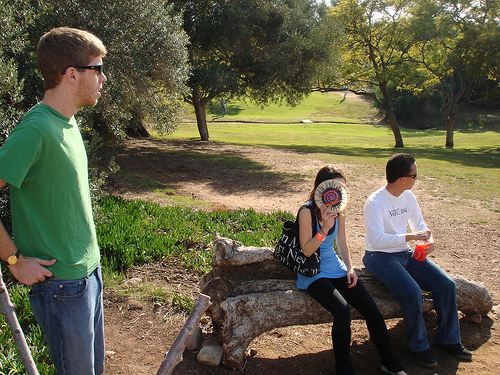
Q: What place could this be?
A: It is a path.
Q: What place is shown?
A: It is a path.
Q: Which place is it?
A: It is a path.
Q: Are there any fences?
A: No, there are no fences.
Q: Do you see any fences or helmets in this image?
A: No, there are no fences or helmets.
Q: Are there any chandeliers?
A: No, there are no chandeliers.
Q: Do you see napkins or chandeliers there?
A: No, there are no chandeliers or napkins.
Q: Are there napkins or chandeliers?
A: No, there are no chandeliers or napkins.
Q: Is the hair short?
A: Yes, the hair is short.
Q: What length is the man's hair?
A: The hair is short.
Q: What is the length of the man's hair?
A: The hair is short.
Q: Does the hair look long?
A: No, the hair is short.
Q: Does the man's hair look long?
A: No, the hair is short.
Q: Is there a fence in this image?
A: No, there are no fences.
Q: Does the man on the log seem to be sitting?
A: Yes, the man is sitting.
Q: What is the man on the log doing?
A: The man is sitting.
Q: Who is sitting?
A: The man is sitting.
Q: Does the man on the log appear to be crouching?
A: No, the man is sitting.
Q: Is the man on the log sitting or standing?
A: The man is sitting.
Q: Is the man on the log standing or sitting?
A: The man is sitting.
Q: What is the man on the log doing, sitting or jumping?
A: The man is sitting.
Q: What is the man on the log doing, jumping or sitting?
A: The man is sitting.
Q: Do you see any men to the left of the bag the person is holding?
A: No, the man is to the right of the bag.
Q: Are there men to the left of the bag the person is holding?
A: No, the man is to the right of the bag.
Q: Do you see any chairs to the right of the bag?
A: No, there is a man to the right of the bag.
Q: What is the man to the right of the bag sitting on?
A: The man is sitting on the log.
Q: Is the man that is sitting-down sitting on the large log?
A: Yes, the man is sitting on the log.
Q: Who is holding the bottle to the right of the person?
A: The man is holding the bottle.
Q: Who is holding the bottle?
A: The man is holding the bottle.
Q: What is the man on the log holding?
A: The man is holding the bottle.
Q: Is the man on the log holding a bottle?
A: Yes, the man is holding a bottle.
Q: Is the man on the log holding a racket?
A: No, the man is holding a bottle.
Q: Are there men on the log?
A: Yes, there is a man on the log.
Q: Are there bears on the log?
A: No, there is a man on the log.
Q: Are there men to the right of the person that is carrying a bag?
A: Yes, there is a man to the right of the person.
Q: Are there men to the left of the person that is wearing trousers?
A: No, the man is to the right of the person.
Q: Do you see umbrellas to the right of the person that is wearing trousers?
A: No, there is a man to the right of the person.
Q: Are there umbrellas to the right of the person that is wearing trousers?
A: No, there is a man to the right of the person.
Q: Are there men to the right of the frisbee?
A: Yes, there is a man to the right of the frisbee.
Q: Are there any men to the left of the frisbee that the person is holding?
A: No, the man is to the right of the frisbee.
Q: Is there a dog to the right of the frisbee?
A: No, there is a man to the right of the frisbee.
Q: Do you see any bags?
A: Yes, there is a bag.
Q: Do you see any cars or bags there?
A: Yes, there is a bag.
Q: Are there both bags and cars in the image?
A: No, there is a bag but no cars.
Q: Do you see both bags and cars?
A: No, there is a bag but no cars.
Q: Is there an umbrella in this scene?
A: No, there are no umbrellas.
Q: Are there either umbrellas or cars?
A: No, there are no umbrellas or cars.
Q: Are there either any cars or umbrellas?
A: No, there are no umbrellas or cars.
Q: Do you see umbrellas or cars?
A: No, there are no umbrellas or cars.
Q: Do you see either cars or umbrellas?
A: No, there are no umbrellas or cars.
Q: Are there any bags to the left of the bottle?
A: Yes, there is a bag to the left of the bottle.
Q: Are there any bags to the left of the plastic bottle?
A: Yes, there is a bag to the left of the bottle.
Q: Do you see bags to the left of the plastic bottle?
A: Yes, there is a bag to the left of the bottle.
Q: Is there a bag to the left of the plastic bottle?
A: Yes, there is a bag to the left of the bottle.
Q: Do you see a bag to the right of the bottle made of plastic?
A: No, the bag is to the left of the bottle.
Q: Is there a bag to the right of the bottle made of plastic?
A: No, the bag is to the left of the bottle.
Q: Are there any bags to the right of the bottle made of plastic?
A: No, the bag is to the left of the bottle.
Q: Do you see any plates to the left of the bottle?
A: No, there is a bag to the left of the bottle.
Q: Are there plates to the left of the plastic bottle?
A: No, there is a bag to the left of the bottle.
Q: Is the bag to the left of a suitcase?
A: No, the bag is to the left of the bottle.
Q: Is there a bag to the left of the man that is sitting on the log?
A: Yes, there is a bag to the left of the man.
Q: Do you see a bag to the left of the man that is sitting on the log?
A: Yes, there is a bag to the left of the man.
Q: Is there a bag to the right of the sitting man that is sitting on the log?
A: No, the bag is to the left of the man.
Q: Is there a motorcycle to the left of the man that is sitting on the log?
A: No, there is a bag to the left of the man.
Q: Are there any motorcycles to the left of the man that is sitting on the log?
A: No, there is a bag to the left of the man.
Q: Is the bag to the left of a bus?
A: No, the bag is to the left of a man.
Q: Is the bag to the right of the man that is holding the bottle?
A: No, the bag is to the left of the man.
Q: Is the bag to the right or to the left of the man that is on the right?
A: The bag is to the left of the man.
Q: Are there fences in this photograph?
A: No, there are no fences.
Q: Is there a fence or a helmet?
A: No, there are no fences or helmets.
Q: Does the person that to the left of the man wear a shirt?
A: Yes, the person wears a shirt.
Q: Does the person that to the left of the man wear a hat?
A: No, the person wears a shirt.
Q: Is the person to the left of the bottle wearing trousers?
A: Yes, the person is wearing trousers.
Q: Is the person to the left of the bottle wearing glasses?
A: No, the person is wearing trousers.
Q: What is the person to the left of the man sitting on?
A: The person is sitting on the log.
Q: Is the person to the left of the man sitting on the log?
A: Yes, the person is sitting on the log.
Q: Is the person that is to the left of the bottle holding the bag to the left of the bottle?
A: Yes, the person is holding the bag.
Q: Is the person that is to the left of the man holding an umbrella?
A: No, the person is holding the bag.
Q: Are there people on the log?
A: Yes, there is a person on the log.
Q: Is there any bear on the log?
A: No, there is a person on the log.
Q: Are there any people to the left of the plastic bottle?
A: Yes, there is a person to the left of the bottle.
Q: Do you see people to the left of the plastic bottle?
A: Yes, there is a person to the left of the bottle.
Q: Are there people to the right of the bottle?
A: No, the person is to the left of the bottle.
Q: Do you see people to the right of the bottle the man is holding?
A: No, the person is to the left of the bottle.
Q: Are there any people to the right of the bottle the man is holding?
A: No, the person is to the left of the bottle.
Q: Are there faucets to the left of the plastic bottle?
A: No, there is a person to the left of the bottle.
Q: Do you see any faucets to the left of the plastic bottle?
A: No, there is a person to the left of the bottle.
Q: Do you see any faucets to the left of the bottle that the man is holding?
A: No, there is a person to the left of the bottle.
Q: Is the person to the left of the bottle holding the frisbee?
A: Yes, the person is holding the frisbee.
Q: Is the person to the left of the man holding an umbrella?
A: No, the person is holding the frisbee.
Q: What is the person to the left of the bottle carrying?
A: The person is carrying a bag.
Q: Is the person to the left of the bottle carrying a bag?
A: Yes, the person is carrying a bag.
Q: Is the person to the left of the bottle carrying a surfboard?
A: No, the person is carrying a bag.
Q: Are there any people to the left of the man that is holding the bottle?
A: Yes, there is a person to the left of the man.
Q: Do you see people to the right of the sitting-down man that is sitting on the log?
A: No, the person is to the left of the man.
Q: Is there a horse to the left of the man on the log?
A: No, there is a person to the left of the man.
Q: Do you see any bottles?
A: Yes, there is a bottle.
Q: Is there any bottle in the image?
A: Yes, there is a bottle.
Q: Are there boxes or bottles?
A: Yes, there is a bottle.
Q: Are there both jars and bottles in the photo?
A: No, there is a bottle but no jars.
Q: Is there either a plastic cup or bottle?
A: Yes, there is a plastic bottle.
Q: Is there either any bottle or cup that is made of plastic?
A: Yes, the bottle is made of plastic.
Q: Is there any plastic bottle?
A: Yes, there is a bottle that is made of plastic.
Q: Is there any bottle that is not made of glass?
A: Yes, there is a bottle that is made of plastic.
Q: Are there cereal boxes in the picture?
A: No, there are no cereal boxes.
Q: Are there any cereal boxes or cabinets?
A: No, there are no cereal boxes or cabinets.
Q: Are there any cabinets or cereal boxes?
A: No, there are no cereal boxes or cabinets.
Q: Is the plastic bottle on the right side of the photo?
A: Yes, the bottle is on the right of the image.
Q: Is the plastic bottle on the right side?
A: Yes, the bottle is on the right of the image.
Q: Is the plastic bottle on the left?
A: No, the bottle is on the right of the image.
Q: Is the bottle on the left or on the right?
A: The bottle is on the right of the image.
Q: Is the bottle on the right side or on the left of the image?
A: The bottle is on the right of the image.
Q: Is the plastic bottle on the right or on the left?
A: The bottle is on the right of the image.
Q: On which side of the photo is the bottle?
A: The bottle is on the right of the image.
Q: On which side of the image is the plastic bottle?
A: The bottle is on the right of the image.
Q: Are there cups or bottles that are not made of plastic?
A: No, there is a bottle but it is made of plastic.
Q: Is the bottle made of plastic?
A: Yes, the bottle is made of plastic.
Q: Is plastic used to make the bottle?
A: Yes, the bottle is made of plastic.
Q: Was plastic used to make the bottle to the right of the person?
A: Yes, the bottle is made of plastic.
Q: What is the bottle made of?
A: The bottle is made of plastic.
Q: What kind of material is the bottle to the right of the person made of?
A: The bottle is made of plastic.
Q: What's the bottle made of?
A: The bottle is made of plastic.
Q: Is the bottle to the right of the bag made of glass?
A: No, the bottle is made of plastic.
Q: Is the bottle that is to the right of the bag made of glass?
A: No, the bottle is made of plastic.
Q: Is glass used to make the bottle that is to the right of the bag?
A: No, the bottle is made of plastic.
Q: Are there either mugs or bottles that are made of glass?
A: No, there is a bottle but it is made of plastic.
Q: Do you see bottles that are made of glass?
A: No, there is a bottle but it is made of plastic.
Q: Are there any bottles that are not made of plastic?
A: No, there is a bottle but it is made of plastic.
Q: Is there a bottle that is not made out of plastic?
A: No, there is a bottle but it is made of plastic.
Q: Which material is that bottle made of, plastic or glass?
A: The bottle is made of plastic.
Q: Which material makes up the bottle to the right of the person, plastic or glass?
A: The bottle is made of plastic.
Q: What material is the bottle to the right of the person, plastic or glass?
A: The bottle is made of plastic.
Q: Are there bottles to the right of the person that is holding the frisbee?
A: Yes, there is a bottle to the right of the person.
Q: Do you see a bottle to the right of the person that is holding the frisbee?
A: Yes, there is a bottle to the right of the person.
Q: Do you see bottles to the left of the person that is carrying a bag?
A: No, the bottle is to the right of the person.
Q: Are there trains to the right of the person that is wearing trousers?
A: No, there is a bottle to the right of the person.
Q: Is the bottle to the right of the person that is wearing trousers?
A: Yes, the bottle is to the right of the person.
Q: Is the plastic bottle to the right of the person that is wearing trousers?
A: Yes, the bottle is to the right of the person.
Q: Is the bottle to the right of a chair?
A: No, the bottle is to the right of the person.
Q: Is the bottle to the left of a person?
A: No, the bottle is to the right of a person.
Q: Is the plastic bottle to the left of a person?
A: No, the bottle is to the right of a person.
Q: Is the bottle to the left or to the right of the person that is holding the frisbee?
A: The bottle is to the right of the person.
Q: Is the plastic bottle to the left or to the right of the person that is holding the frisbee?
A: The bottle is to the right of the person.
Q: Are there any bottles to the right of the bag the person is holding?
A: Yes, there is a bottle to the right of the bag.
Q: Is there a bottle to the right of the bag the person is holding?
A: Yes, there is a bottle to the right of the bag.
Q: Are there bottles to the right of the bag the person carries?
A: Yes, there is a bottle to the right of the bag.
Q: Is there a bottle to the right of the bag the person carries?
A: Yes, there is a bottle to the right of the bag.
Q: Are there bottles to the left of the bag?
A: No, the bottle is to the right of the bag.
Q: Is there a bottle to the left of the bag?
A: No, the bottle is to the right of the bag.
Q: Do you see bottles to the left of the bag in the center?
A: No, the bottle is to the right of the bag.